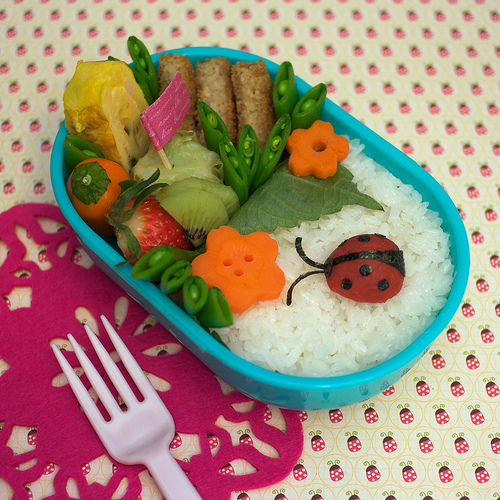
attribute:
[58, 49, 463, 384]
container — blue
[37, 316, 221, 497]
fork — plastic, white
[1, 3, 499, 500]
table — bright